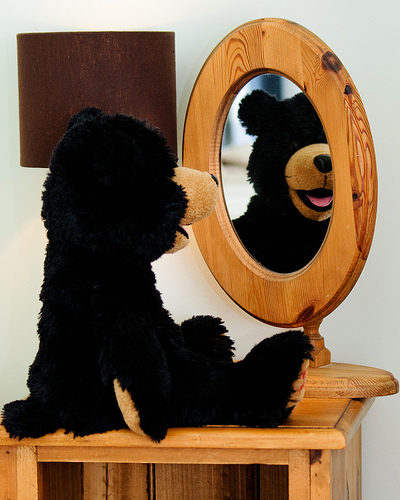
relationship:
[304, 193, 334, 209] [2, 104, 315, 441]
pink tongue in bear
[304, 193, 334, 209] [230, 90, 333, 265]
pink tongue sticking out of a bear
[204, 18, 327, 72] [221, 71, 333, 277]
frame of mirror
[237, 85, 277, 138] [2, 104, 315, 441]
ear of bear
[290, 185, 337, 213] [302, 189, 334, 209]
mouth and tongue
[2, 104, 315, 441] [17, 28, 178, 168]
bear and shade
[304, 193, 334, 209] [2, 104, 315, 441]
pink tongue sticking out of bear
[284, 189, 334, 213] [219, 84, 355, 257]
pink tongue sticking out of bear